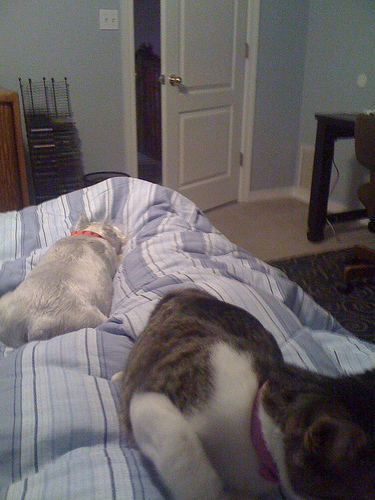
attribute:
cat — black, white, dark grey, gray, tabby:
[114, 283, 373, 498]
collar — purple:
[244, 375, 283, 477]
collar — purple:
[248, 376, 285, 484]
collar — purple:
[249, 378, 279, 485]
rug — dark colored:
[272, 212, 372, 342]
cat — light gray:
[5, 201, 128, 342]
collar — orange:
[70, 226, 105, 241]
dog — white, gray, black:
[1, 217, 133, 352]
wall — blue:
[13, 18, 86, 58]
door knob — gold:
[160, 71, 195, 89]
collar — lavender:
[222, 364, 299, 490]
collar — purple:
[248, 369, 279, 484]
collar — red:
[67, 228, 106, 239]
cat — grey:
[8, 203, 134, 332]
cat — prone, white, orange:
[1, 216, 130, 345]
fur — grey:
[62, 281, 76, 294]